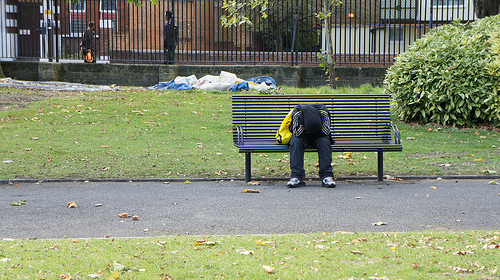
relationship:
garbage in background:
[148, 70, 278, 95] [9, 10, 384, 85]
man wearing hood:
[277, 103, 338, 188] [298, 109, 327, 139]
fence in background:
[0, 0, 477, 66] [5, 5, 485, 89]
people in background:
[71, 6, 190, 63] [5, 5, 485, 89]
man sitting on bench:
[277, 103, 338, 188] [227, 89, 407, 183]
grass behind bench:
[1, 82, 498, 177] [227, 89, 407, 183]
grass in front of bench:
[0, 227, 498, 276] [227, 89, 407, 183]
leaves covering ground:
[239, 247, 283, 279] [4, 150, 484, 243]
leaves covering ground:
[312, 237, 368, 261] [373, 246, 437, 277]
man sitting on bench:
[283, 96, 340, 193] [227, 89, 407, 183]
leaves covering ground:
[66, 197, 142, 224] [3, 77, 499, 278]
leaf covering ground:
[103, 166, 112, 173] [3, 77, 499, 278]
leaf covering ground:
[434, 158, 454, 171] [3, 77, 499, 278]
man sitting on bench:
[277, 103, 338, 188] [232, 95, 404, 183]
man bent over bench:
[277, 103, 338, 188] [227, 89, 407, 183]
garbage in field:
[150, 70, 279, 95] [0, 76, 498, 173]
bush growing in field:
[384, 23, 474, 139] [0, 76, 498, 173]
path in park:
[1, 180, 497, 236] [8, 64, 480, 238]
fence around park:
[0, 0, 498, 70] [0, 80, 497, 280]